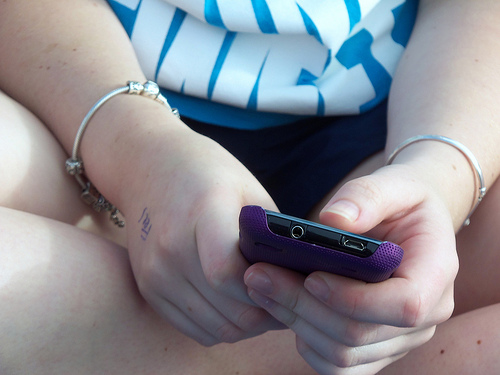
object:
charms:
[126, 79, 181, 120]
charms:
[64, 156, 124, 228]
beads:
[64, 159, 125, 228]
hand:
[123, 139, 292, 348]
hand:
[243, 159, 459, 375]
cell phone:
[238, 204, 405, 283]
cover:
[254, 240, 283, 253]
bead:
[143, 80, 160, 100]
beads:
[127, 80, 167, 105]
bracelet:
[62, 78, 183, 229]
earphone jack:
[291, 226, 304, 239]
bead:
[478, 187, 487, 202]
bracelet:
[382, 132, 487, 235]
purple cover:
[237, 205, 404, 283]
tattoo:
[137, 205, 153, 242]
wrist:
[388, 139, 474, 233]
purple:
[238, 204, 405, 283]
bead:
[63, 159, 83, 175]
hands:
[127, 140, 458, 375]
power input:
[344, 238, 365, 250]